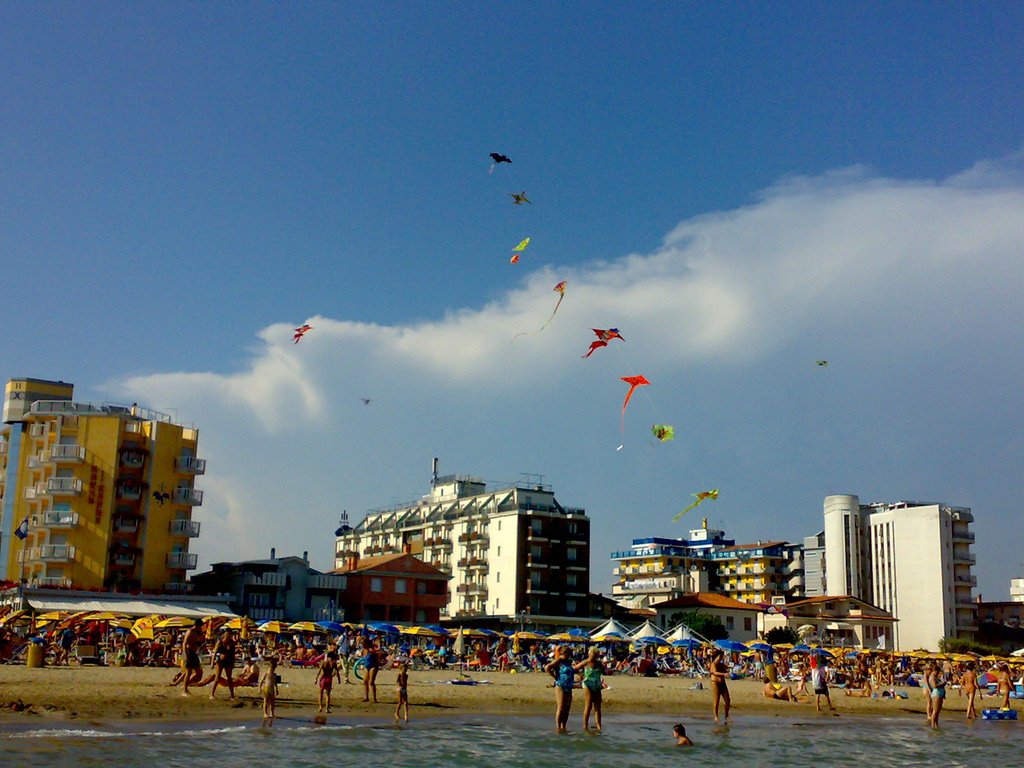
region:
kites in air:
[470, 87, 720, 457]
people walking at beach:
[106, 597, 729, 721]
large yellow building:
[28, 385, 222, 594]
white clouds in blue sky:
[391, 416, 455, 461]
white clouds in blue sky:
[732, 276, 777, 311]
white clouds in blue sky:
[903, 315, 980, 385]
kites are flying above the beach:
[463, 127, 707, 495]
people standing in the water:
[543, 626, 635, 766]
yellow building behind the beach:
[12, 380, 210, 603]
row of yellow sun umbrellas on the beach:
[30, 604, 234, 639]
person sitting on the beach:
[227, 650, 260, 692]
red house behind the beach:
[349, 534, 461, 630]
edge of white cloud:
[678, 142, 953, 223]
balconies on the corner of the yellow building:
[167, 439, 210, 580]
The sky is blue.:
[136, 81, 343, 186]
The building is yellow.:
[27, 397, 195, 566]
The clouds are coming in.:
[747, 240, 1020, 498]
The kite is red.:
[610, 367, 656, 415]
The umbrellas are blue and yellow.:
[279, 610, 451, 680]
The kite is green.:
[624, 413, 716, 474]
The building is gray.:
[870, 505, 966, 610]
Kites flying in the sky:
[245, 85, 934, 678]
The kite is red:
[602, 332, 688, 446]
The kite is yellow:
[487, 212, 555, 301]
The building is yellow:
[1, 347, 265, 680]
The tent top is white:
[588, 593, 782, 701]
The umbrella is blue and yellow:
[289, 610, 347, 653]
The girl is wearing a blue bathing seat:
[523, 625, 594, 750]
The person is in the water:
[645, 688, 743, 752]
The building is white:
[801, 404, 988, 734]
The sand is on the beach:
[46, 626, 796, 766]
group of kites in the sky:
[493, 184, 754, 524]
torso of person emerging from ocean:
[657, 717, 703, 760]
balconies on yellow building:
[164, 440, 218, 597]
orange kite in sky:
[609, 356, 651, 429]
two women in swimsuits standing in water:
[528, 641, 612, 740]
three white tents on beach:
[582, 610, 712, 643]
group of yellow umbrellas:
[22, 601, 257, 643]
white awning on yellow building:
[18, 582, 247, 627]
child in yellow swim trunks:
[247, 654, 289, 730]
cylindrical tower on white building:
[816, 485, 873, 612]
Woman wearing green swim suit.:
[570, 621, 624, 748]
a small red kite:
[608, 354, 656, 430]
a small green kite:
[634, 411, 691, 466]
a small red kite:
[563, 313, 630, 365]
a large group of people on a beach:
[277, 597, 1001, 753]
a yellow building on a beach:
[19, 357, 204, 623]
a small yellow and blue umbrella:
[250, 604, 298, 642]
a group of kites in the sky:
[453, 111, 774, 527]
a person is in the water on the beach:
[696, 636, 751, 760]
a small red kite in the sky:
[273, 310, 328, 375]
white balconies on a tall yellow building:
[0, 375, 210, 591]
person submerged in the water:
[667, 722, 691, 746]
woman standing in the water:
[572, 650, 612, 734]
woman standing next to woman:
[537, 644, 582, 733]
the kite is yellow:
[645, 419, 674, 446]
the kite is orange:
[614, 371, 653, 413]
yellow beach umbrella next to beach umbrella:
[150, 614, 196, 635]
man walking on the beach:
[177, 614, 212, 700]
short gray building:
[185, 548, 350, 621]